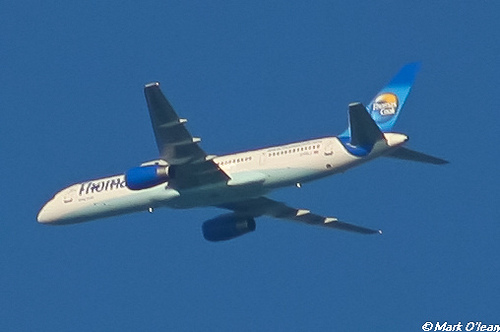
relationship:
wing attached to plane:
[129, 67, 233, 202] [14, 52, 460, 287]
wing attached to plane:
[224, 178, 404, 250] [18, 15, 482, 286]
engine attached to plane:
[113, 156, 188, 194] [53, 114, 360, 214]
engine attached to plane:
[202, 212, 255, 241] [38, 61, 451, 240]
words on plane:
[79, 177, 133, 195] [72, 80, 342, 242]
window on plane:
[256, 135, 326, 159] [1, 70, 431, 252]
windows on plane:
[225, 151, 265, 173] [30, 76, 441, 243]